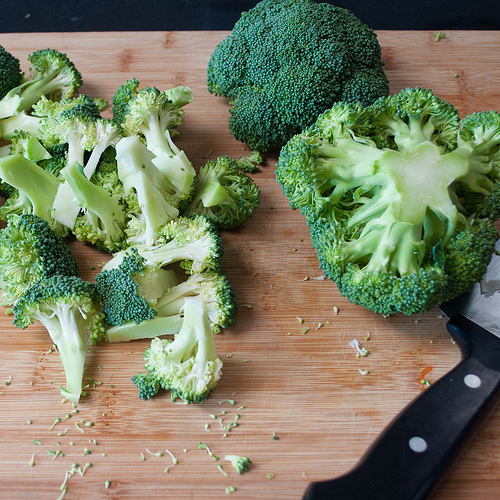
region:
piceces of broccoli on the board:
[26, 412, 275, 497]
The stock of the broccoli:
[167, 292, 217, 354]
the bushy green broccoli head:
[0, 213, 103, 317]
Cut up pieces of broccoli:
[1, 43, 200, 398]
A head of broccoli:
[298, 97, 498, 304]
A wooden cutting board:
[84, 40, 206, 82]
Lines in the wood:
[285, 351, 349, 400]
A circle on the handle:
[407, 432, 432, 452]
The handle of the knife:
[299, 338, 498, 498]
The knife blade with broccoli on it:
[442, 262, 499, 322]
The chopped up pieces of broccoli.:
[13, 54, 240, 394]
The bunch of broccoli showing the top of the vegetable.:
[206, 4, 396, 150]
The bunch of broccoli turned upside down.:
[266, 95, 497, 321]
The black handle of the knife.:
[287, 326, 499, 488]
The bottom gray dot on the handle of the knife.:
[406, 433, 429, 461]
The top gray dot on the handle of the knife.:
[459, 364, 480, 387]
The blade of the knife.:
[428, 232, 497, 315]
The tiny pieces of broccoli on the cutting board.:
[4, 284, 456, 499]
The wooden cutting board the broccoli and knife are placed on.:
[4, 31, 499, 499]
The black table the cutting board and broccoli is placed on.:
[2, 1, 499, 28]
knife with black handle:
[321, 263, 499, 497]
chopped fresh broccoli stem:
[148, 288, 235, 407]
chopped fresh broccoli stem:
[12, 275, 102, 405]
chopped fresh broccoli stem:
[105, 133, 180, 248]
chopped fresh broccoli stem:
[186, 148, 266, 227]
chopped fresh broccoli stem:
[271, 84, 486, 317]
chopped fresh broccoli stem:
[30, 143, 129, 248]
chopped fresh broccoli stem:
[204, 3, 390, 160]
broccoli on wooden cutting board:
[23, 37, 451, 467]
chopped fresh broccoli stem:
[3, 48, 106, 129]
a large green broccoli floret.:
[203, 3, 400, 150]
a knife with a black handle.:
[297, 237, 498, 496]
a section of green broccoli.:
[125, 301, 242, 413]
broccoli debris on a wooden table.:
[20, 401, 292, 495]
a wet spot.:
[328, 361, 410, 407]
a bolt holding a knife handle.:
[402, 433, 431, 456]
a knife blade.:
[465, 257, 498, 346]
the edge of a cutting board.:
[3, 0, 498, 35]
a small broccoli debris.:
[148, 458, 184, 492]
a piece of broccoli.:
[113, 64, 212, 206]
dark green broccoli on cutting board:
[206, 5, 391, 162]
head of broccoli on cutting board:
[277, 90, 492, 315]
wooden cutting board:
[0, 25, 495, 495]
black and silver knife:
[295, 235, 495, 492]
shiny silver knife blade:
[465, 235, 496, 330]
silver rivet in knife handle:
[460, 370, 476, 385]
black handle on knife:
[300, 310, 495, 490]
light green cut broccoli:
[130, 295, 220, 405]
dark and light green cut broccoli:
[5, 270, 105, 400]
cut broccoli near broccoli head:
[186, 153, 261, 231]